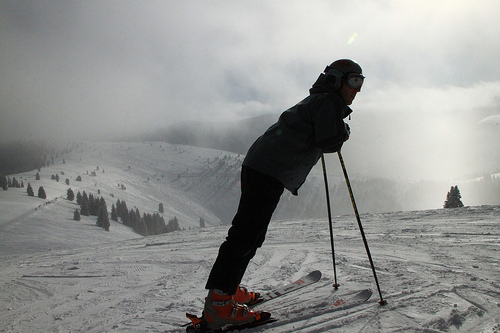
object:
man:
[201, 59, 364, 330]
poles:
[335, 148, 390, 306]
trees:
[95, 204, 108, 227]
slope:
[2, 170, 228, 260]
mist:
[2, 2, 246, 156]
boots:
[201, 289, 273, 330]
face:
[342, 70, 362, 105]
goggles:
[345, 75, 364, 92]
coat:
[242, 96, 353, 197]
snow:
[0, 134, 499, 332]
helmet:
[325, 57, 362, 80]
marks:
[373, 219, 499, 333]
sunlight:
[278, 2, 473, 45]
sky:
[3, 0, 499, 141]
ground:
[3, 206, 499, 331]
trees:
[38, 185, 47, 199]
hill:
[2, 119, 497, 330]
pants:
[204, 164, 285, 291]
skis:
[183, 288, 373, 332]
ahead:
[316, 58, 365, 106]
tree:
[444, 185, 466, 208]